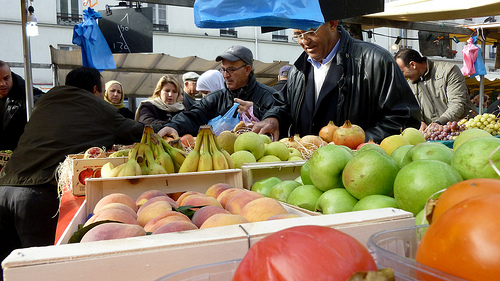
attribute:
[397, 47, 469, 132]
man — balding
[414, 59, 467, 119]
jacket — tan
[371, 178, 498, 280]
box — plastic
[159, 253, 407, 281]
box — plastic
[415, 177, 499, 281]
tomatoes — fresh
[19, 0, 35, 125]
pole — gray, metal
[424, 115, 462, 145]
grapes — red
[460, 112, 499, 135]
grapes — green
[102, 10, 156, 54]
sign — black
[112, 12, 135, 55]
prices — white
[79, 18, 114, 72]
bag — plastic, blue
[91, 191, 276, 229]
peaches — red, fresh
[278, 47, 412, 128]
jacket — black, dark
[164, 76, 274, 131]
jacket — black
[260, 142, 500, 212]
apples — green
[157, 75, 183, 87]
hair — blonde